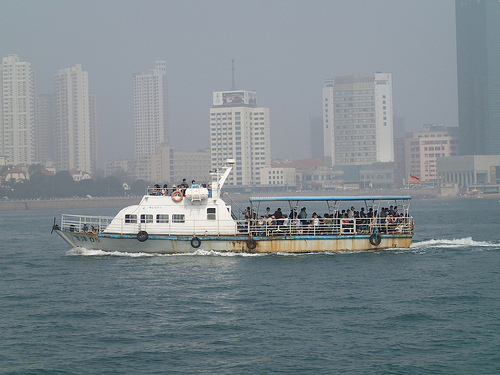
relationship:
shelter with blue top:
[255, 197, 411, 253] [242, 185, 415, 203]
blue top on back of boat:
[242, 185, 415, 203] [59, 180, 434, 259]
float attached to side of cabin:
[171, 189, 183, 202] [102, 196, 234, 218]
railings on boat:
[68, 209, 420, 238] [32, 150, 491, 260]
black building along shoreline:
[455, 0, 490, 154] [300, 155, 490, 193]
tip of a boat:
[50, 209, 73, 239] [50, 159, 420, 257]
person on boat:
[241, 206, 253, 238] [50, 159, 420, 257]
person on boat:
[162, 183, 170, 194] [50, 159, 420, 257]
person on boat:
[150, 182, 162, 195] [50, 159, 420, 257]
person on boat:
[356, 205, 366, 232] [50, 159, 420, 257]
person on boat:
[262, 203, 277, 220] [50, 159, 420, 257]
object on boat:
[182, 231, 253, 283] [19, 154, 420, 301]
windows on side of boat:
[124, 212, 186, 225] [50, 159, 420, 257]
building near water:
[314, 70, 396, 169] [2, 200, 499, 373]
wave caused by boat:
[63, 234, 498, 259] [50, 159, 420, 257]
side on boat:
[222, 235, 410, 252] [37, 148, 427, 266]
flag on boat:
[404, 169, 422, 189] [44, 154, 418, 261]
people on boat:
[151, 178, 215, 197] [37, 148, 427, 266]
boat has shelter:
[50, 159, 420, 257] [247, 194, 413, 201]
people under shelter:
[242, 206, 415, 233] [247, 194, 413, 201]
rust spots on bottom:
[227, 188, 371, 242] [227, 240, 412, 250]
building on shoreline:
[0, 52, 40, 169] [10, 183, 495, 216]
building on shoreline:
[55, 61, 99, 177] [10, 183, 495, 216]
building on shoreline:
[128, 52, 169, 185] [10, 183, 495, 216]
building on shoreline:
[208, 90, 272, 187] [10, 183, 495, 216]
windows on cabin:
[123, 210, 188, 225] [101, 193, 243, 235]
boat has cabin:
[50, 159, 420, 257] [101, 193, 243, 235]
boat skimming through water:
[52, 182, 412, 282] [2, 200, 499, 373]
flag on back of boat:
[408, 173, 420, 183] [53, 145, 423, 285]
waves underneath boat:
[49, 240, 124, 267] [97, 157, 415, 255]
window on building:
[382, 89, 389, 141] [321, 67, 398, 170]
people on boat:
[242, 205, 415, 233] [44, 149, 421, 254]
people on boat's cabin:
[142, 168, 224, 197] [108, 156, 238, 240]